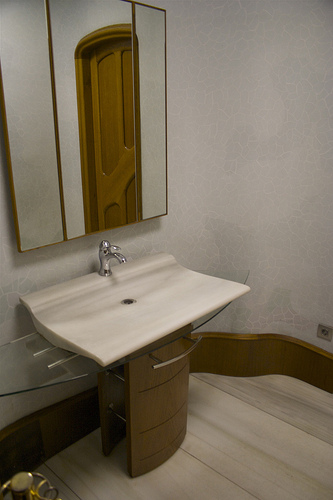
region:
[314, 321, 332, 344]
Electrical outlit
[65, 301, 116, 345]
A white colored sink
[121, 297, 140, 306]
Silver drain at the bottom of sink.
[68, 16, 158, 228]
Reflection of door in mirror.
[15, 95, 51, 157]
A glass mirror hanging on a wall.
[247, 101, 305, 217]
A white wall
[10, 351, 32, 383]
Clear glass counter next to sink.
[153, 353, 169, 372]
A metal hand towel rack under sink.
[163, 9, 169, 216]
Brown wooden trim around mirror.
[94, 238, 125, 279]
Silver faucet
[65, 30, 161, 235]
door's reflection in the mirror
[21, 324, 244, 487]
Modern sink stand with glass metal and wood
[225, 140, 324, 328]
Light blue and white giraffe pattern wallpaper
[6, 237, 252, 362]
Large rectangular porcelain sink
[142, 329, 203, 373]
Bow shaped silver towel holder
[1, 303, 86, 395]
Clear glass shelf with metal supports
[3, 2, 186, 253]
Medicine cabinet with three doors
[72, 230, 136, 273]
Bright silver sink fixture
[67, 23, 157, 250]
Reflection of wooden door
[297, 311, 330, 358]
Small metal electrical outlet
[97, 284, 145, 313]
Light silver sink drain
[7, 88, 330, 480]
The bathroom is very modern.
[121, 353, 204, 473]
There are no drawers on the sink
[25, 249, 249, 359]
The sink is modern and white.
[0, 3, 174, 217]
The mirror is large.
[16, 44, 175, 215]
The mirror shows the door.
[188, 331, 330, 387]
There is a modern decorative boarder.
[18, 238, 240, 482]
The vanity is white and tan.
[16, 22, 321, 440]
The bathroom is plain with little in it.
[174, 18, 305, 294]
The wall has some texture to it.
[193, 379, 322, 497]
The floor is wood.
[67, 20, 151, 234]
a brown wood door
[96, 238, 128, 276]
a silver faucet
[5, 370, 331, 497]
a pale wood floor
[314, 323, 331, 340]
a plug in on a wall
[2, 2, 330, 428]
pale grey patterned wall paper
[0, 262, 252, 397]
a glass table under a sink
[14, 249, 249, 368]
a white sink in a bathroom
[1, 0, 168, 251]
a mirror on a bathroom wall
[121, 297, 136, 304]
a drain in a sink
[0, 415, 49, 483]
a vent in a wall